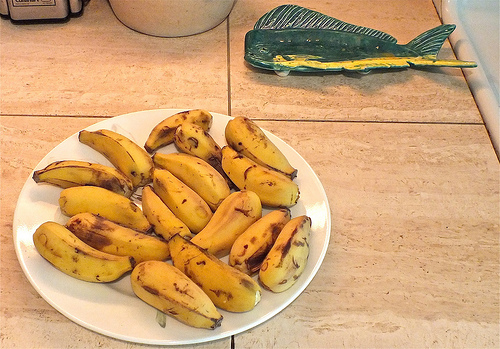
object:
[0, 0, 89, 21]
silver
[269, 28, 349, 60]
gills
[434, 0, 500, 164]
wall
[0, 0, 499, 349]
ground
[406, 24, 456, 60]
fins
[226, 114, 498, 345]
tile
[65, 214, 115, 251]
buising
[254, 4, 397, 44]
fins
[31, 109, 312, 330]
banana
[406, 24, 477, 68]
fish tail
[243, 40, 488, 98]
shadow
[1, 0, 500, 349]
floor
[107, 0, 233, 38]
pan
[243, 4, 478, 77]
fish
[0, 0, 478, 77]
background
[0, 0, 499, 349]
photo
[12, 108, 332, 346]
plate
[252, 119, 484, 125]
line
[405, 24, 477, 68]
decoration